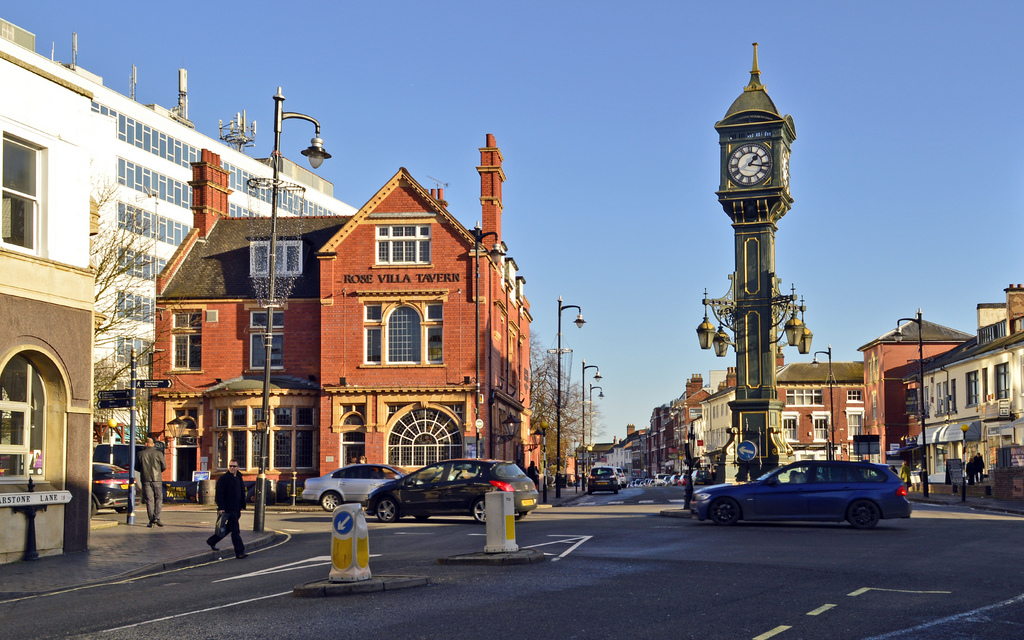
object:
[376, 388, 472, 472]
windows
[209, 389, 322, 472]
windows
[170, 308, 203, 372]
window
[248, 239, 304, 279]
window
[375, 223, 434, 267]
window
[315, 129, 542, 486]
building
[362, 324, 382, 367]
window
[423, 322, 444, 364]
window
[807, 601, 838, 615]
lines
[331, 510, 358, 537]
sign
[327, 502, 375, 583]
curb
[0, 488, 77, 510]
sign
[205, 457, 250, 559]
man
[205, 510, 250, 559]
legs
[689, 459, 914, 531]
car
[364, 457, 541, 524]
car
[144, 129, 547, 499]
building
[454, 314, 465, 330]
brick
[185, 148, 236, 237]
chimney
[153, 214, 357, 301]
roof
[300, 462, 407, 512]
cars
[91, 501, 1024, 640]
street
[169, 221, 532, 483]
window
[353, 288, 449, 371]
window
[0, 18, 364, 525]
building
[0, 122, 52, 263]
window